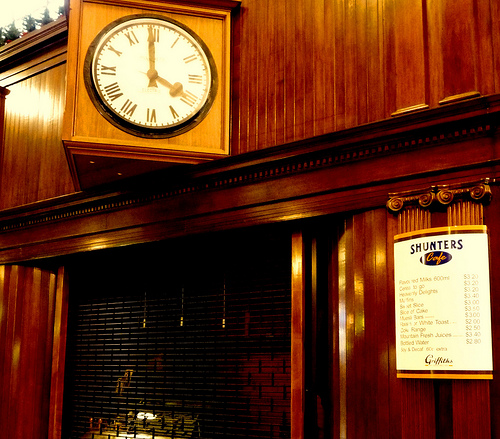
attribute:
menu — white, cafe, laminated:
[386, 189, 499, 380]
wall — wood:
[226, 4, 497, 438]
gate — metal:
[52, 256, 288, 434]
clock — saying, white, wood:
[74, 9, 243, 137]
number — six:
[139, 104, 167, 129]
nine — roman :
[99, 55, 126, 88]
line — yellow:
[417, 212, 457, 243]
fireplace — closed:
[84, 394, 225, 437]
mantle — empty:
[271, 112, 365, 183]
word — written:
[400, 227, 471, 260]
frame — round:
[178, 114, 192, 135]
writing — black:
[406, 280, 459, 355]